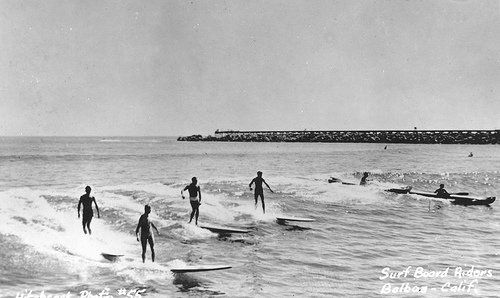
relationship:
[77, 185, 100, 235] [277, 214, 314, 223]
person standing on surfboard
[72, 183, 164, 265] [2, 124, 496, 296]
people in ocean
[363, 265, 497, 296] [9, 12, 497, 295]
white text on photo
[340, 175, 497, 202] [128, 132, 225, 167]
boat in water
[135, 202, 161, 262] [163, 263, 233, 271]
person on surfboard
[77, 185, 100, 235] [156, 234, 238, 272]
person on surfboard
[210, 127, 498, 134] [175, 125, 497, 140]
railing on edge promontory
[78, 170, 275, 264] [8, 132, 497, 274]
surfers in water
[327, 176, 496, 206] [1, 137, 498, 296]
boat on water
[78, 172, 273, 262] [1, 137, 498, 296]
surfers on water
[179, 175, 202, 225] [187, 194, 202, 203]
person has white shorts